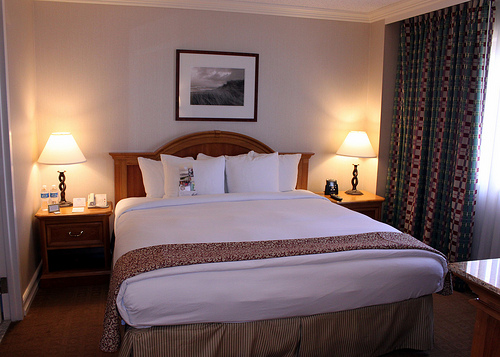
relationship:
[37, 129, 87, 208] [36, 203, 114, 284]
lamp on stand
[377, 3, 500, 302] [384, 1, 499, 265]
window has curtains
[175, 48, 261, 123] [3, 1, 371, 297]
photo on wall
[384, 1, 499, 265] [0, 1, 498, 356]
curtains in room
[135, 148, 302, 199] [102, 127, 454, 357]
pillows on bed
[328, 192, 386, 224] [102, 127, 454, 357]
table next to bed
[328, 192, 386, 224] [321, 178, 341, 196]
table has telephone